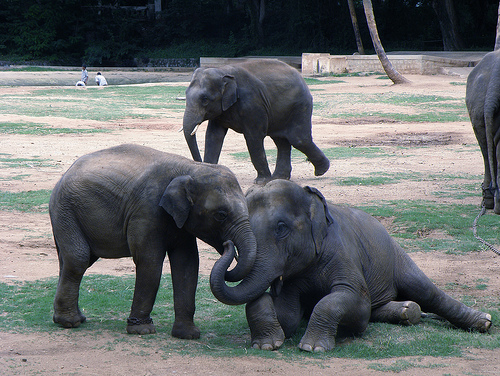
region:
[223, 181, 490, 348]
the elephant is laying down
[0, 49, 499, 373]
many elephants on the grass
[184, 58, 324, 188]
the elephant is walking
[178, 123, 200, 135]
the elephant has tusks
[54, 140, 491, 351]
the elephants are playing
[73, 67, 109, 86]
people are in the distance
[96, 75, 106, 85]
people wears a white shirt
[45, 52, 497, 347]
the elephants have long trunks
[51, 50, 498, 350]
the elephants are gray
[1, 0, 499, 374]
the scene takes place outdoors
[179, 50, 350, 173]
GRAY ELEPHANT IN ANIMAL AREA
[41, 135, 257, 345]
GRAY ELEPHANT IN ANIMAL AREA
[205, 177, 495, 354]
GRAY ELEPHANT IN ANIMAL AREA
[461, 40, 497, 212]
PART OF GRAY ELEPHANT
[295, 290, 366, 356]
LEFG OF GRAY ELEPHANT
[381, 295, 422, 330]
PART OF GRAY ELEPHANT FOOT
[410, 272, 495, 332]
LEG OF GRAY ELEPHANT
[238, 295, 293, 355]
LEG OF GRAY ELEPHANT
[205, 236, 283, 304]
TRUNK OF GRAY ELEPHANT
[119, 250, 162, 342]
LEG OF GRAY ELEPHANT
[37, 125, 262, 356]
this is an elephant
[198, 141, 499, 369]
the elephants is grey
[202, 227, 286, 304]
the trunk of the elephant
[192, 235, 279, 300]
elephant trunck curved up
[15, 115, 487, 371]
two elephants are playing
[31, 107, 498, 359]
two young baby elephants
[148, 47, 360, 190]
elephant in background walking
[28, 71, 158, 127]
a patch of grass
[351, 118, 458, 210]
brown patch of dirt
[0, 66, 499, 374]
a field of dirt and green grass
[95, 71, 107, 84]
a person in the field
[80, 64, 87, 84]
a person in the field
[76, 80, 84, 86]
a person in the field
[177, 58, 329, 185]
an elephant in the field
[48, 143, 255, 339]
an elephant in the field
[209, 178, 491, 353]
an elephant in the field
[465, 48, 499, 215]
an elephant in the field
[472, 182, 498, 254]
a chain on an elephant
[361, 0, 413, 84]
a tree in the field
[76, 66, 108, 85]
people standing behind the elephants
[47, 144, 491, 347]
two baby elephants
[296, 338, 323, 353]
elephant toe nails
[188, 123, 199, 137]
small tusk on the elephant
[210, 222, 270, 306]
trunks are touching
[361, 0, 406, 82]
palm tree trunk is curved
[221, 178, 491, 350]
elephant is laying down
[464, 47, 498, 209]
rear end of an elephant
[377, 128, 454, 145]
puddle of mud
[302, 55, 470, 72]
a small stone wall